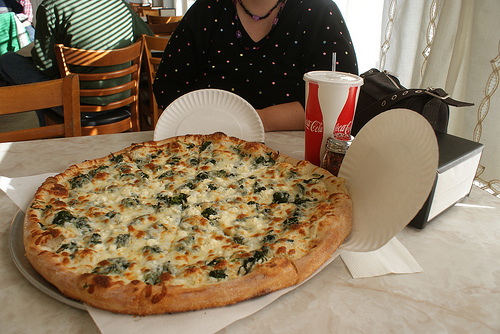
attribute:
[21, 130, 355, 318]
pizza — cheese, spinach, whole, round, large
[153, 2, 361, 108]
shirt — polk dot, black, poka dots, polka dots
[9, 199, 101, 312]
pan — silver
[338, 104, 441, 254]
plate — paper, white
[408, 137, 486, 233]
holder — black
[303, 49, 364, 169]
cup — red, white, paper, disposable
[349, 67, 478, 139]
purse — black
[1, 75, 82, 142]
chair — brown, wooden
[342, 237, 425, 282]
napkin — white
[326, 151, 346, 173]
pepper — flakes, red